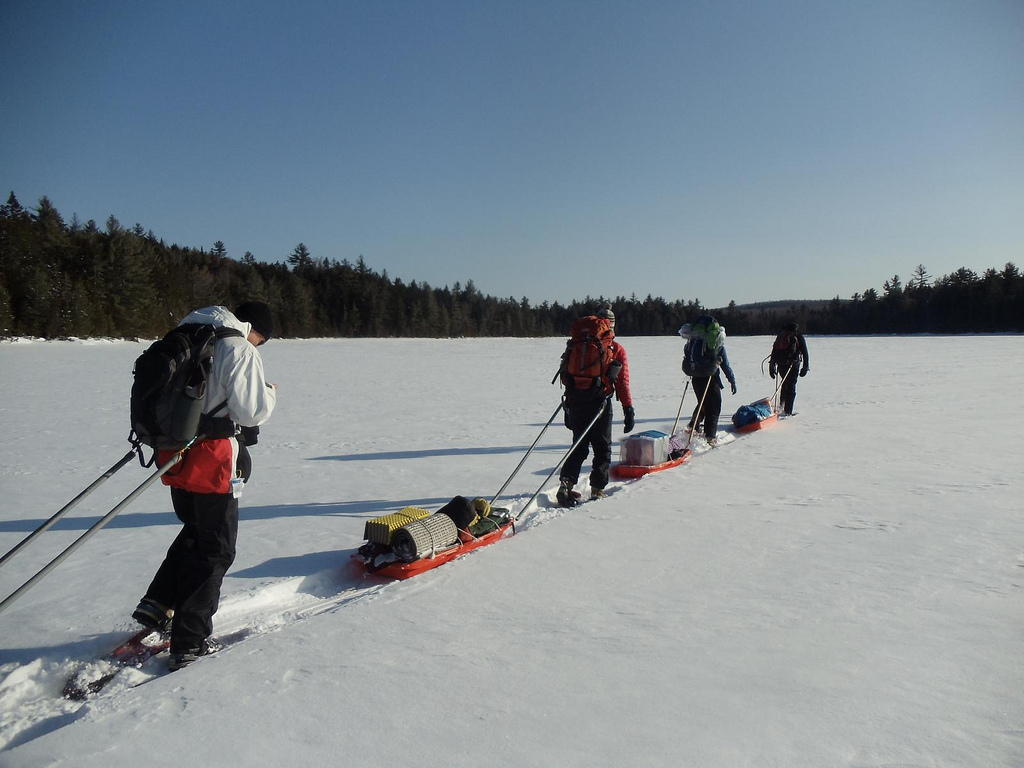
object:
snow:
[579, 515, 1013, 646]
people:
[100, 299, 1013, 646]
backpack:
[128, 319, 245, 447]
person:
[132, 311, 283, 497]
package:
[362, 493, 517, 583]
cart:
[347, 463, 530, 582]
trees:
[80, 214, 1006, 345]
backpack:
[552, 327, 615, 401]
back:
[554, 332, 619, 418]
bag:
[724, 392, 785, 435]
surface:
[714, 390, 801, 439]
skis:
[48, 588, 322, 706]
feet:
[114, 590, 275, 676]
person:
[125, 294, 287, 674]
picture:
[39, 112, 783, 694]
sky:
[227, 53, 774, 275]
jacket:
[133, 307, 280, 497]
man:
[551, 307, 634, 507]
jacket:
[551, 321, 634, 401]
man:
[93, 323, 312, 551]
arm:
[221, 327, 276, 425]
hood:
[169, 284, 285, 395]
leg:
[130, 486, 242, 641]